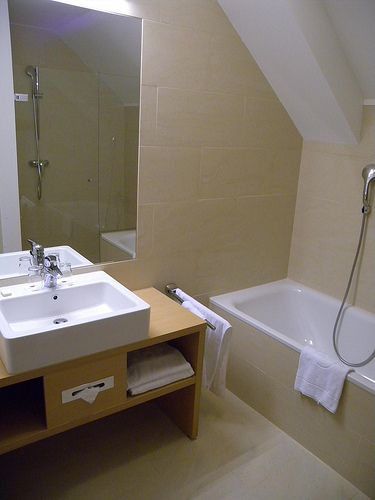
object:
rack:
[165, 283, 228, 331]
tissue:
[73, 386, 99, 405]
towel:
[174, 287, 233, 399]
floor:
[204, 428, 296, 479]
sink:
[0, 270, 151, 375]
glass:
[18, 174, 88, 268]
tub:
[208, 277, 375, 500]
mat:
[128, 407, 286, 458]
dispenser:
[61, 375, 115, 405]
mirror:
[0, 0, 142, 279]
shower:
[362, 162, 375, 205]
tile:
[198, 146, 275, 200]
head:
[362, 163, 375, 205]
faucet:
[43, 255, 64, 288]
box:
[43, 352, 128, 429]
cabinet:
[0, 286, 208, 456]